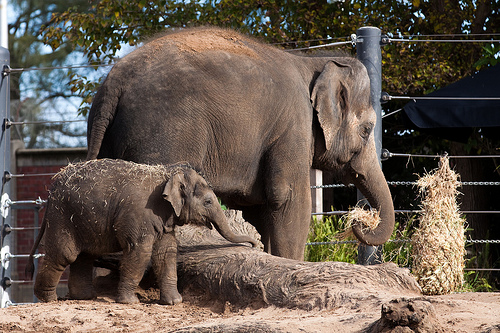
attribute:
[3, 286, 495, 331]
ground — dirt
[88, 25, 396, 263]
elephant — larger, adult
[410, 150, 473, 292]
basket — wire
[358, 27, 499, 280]
fence — wire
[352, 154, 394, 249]
trunk — larger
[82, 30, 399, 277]
elephant — adult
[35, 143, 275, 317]
elephant — large 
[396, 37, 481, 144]
fence — tall 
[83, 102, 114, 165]
tail — larger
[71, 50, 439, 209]
elephant — baby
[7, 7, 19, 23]
sky — blue, light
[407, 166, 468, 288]
tree trunk — shreded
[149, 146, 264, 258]
head — elephant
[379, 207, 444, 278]
grass — wild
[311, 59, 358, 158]
ear — elephant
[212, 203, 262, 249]
trunk — smaller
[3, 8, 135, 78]
branch — leafy, green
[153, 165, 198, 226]
elephant — baby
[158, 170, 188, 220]
ear — small, floppy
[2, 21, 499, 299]
fence — metal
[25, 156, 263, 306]
elephant — baby, adult, small 